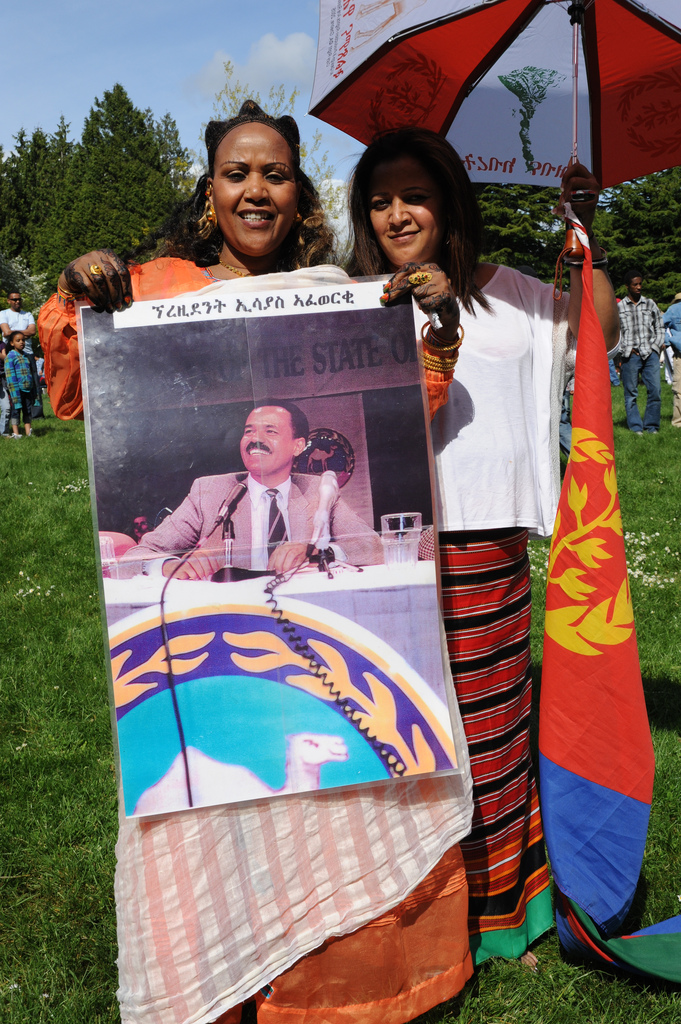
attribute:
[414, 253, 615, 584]
shirt — white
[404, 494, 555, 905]
skirt — colorful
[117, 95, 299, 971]
woman — in orange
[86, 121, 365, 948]
woman — in orange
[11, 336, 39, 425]
child — standing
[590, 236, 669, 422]
man — of african descent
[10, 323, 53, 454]
child — green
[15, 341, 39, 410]
sweater — blue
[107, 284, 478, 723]
picture — of a man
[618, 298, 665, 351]
shirt — plaid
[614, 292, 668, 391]
shirt — plaid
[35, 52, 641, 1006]
women —  long clothing.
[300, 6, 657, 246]
umbrella — white , red 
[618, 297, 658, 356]
shirt — plaid 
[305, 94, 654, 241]
umbrella — red, white